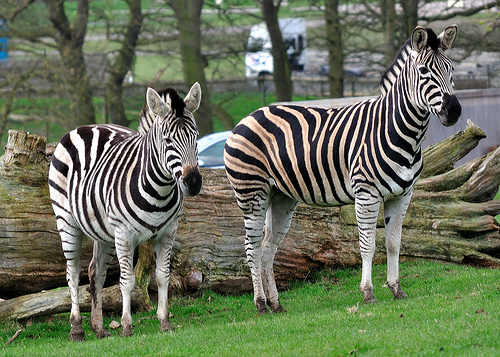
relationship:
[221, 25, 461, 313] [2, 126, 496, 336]
zebra in front of tree trunk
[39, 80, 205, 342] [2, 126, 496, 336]
zebra in front of tree trunk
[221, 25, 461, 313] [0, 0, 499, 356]
zebra standing in grass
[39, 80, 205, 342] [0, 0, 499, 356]
zebra standing in grass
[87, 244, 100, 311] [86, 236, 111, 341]
tail next to leg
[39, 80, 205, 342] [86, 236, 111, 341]
zebra has leg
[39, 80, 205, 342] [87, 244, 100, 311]
zebra has tail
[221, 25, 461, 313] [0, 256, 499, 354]
zebra standing in grass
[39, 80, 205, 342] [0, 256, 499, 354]
zebra standing in grass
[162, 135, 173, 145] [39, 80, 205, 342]
eye on zebra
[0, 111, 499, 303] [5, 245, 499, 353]
log lying on ground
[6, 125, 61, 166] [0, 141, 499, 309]
stump on log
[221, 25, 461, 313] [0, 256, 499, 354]
zebra standing on grass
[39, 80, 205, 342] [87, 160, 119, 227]
zebra with stripes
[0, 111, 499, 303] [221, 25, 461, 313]
log behind zebra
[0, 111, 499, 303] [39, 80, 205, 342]
log behind zebra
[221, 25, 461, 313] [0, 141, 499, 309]
zebra standing in front of log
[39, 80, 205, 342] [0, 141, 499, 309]
zebra standing in front of log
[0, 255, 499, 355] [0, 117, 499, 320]
patch on side of log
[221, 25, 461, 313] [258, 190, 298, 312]
zebra has leg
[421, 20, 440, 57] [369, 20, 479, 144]
mane on head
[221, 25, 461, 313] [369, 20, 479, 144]
zebra has head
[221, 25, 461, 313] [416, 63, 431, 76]
zebra has right eye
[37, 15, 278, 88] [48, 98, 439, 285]
trees by zebras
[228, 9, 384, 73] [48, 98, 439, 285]
vehicles by zebras